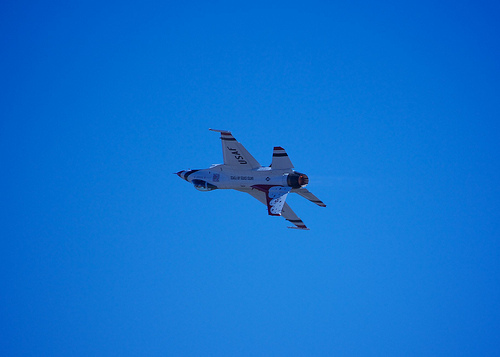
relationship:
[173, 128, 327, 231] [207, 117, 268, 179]
jet has wing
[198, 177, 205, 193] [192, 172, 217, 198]
pilot inside of cockpit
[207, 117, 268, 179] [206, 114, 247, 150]
wing has stripes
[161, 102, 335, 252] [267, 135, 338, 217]
jet has tail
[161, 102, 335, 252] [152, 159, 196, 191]
jet has nose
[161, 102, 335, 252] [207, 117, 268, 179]
jet has wing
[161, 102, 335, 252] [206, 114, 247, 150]
jet has stripes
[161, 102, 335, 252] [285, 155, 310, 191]
jet has afterburner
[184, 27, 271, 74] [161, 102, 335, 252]
sky has jet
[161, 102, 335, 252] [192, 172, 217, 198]
jet has cockpit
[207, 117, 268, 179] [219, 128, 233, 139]
wing has tip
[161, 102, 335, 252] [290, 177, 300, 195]
jet has engine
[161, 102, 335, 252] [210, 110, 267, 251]
jet has wingspan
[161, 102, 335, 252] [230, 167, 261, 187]
jet has writing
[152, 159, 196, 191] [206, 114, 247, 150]
nose has stripes